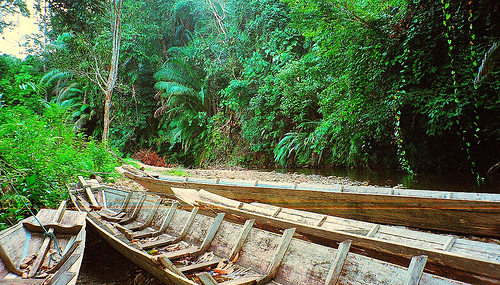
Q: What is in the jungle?
A: Wooden boats.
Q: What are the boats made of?
A: Wood.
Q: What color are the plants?
A: Green.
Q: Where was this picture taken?
A: In a jungle.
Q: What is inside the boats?
A: Debris.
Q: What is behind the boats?
A: A bush.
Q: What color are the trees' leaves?
A: Green.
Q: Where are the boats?
A: In the jungle.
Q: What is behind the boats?
A: Plants and trees.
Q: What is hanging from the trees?
A: Vines.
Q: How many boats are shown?
A: Four.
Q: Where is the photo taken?
A: A forest.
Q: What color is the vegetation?
A: Green.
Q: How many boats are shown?
A: 4.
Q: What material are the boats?
A: Wood.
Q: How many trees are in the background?
A: 1.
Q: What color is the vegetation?
A: Green.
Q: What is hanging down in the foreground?
A: Ivy.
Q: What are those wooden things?
A: Canoes.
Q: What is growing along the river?
A: Trees.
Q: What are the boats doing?
A: Laying down.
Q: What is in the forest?
A: Trees.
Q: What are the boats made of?
A: Wood.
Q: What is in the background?
A: Trees.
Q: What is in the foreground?
A: Boats.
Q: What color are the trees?
A: Green.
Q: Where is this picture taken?
A: In the forest.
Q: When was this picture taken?
A: Daytime.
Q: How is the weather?
A: Clear.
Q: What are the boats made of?
A: Wood.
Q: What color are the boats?
A: Brown.